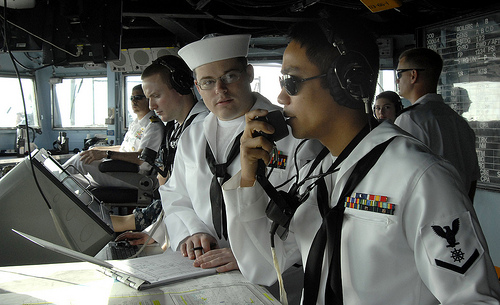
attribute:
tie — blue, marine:
[206, 136, 242, 238]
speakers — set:
[106, 46, 183, 73]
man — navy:
[162, 41, 280, 293]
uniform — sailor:
[225, 126, 484, 303]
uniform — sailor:
[390, 91, 482, 201]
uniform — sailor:
[158, 30, 303, 247]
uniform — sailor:
[115, 110, 166, 160]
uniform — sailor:
[160, 95, 207, 176]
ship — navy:
[2, 0, 499, 302]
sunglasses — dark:
[274, 72, 327, 94]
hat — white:
[178, 32, 251, 72]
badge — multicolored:
[342, 192, 398, 214]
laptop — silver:
[28, 150, 160, 240]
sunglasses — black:
[278, 67, 326, 94]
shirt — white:
[220, 119, 498, 302]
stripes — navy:
[340, 192, 396, 218]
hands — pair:
[174, 233, 238, 273]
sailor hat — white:
[179, 30, 265, 79]